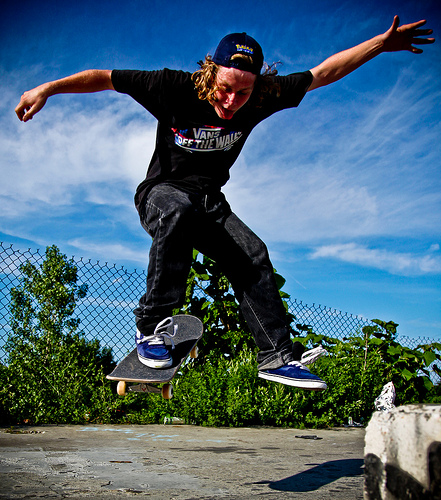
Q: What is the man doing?
A: Skateboarding.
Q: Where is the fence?
A: Behind the bushes.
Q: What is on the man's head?
A: Baseball cap.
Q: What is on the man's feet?
A: Two blue tennis shoes with white laces.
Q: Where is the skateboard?
A: In the air.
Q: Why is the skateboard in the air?
A: The man is doing a trick.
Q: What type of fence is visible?
A: Chain link.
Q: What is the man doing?
A: Skateboarding.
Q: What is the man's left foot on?
A: A skateboard.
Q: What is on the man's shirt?
A: White writing.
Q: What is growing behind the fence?
A: Trees and bushes.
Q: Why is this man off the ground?
A: He is skateboarding.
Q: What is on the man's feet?
A: Blue shoes.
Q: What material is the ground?
A: Cement.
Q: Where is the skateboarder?
A: In the air.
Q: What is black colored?
A: Skateboard.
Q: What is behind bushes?
A: Metal fence.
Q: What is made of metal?
A: The fence.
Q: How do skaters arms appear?
A: Extended out.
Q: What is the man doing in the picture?
A: Skateboarding.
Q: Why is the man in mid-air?
A: The man is performing a trick.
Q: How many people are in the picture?
A: One person.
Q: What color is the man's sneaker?
A: Blue.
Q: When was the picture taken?
A: Daytime.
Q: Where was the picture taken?
A: In the park.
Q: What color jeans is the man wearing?
A: Blue.